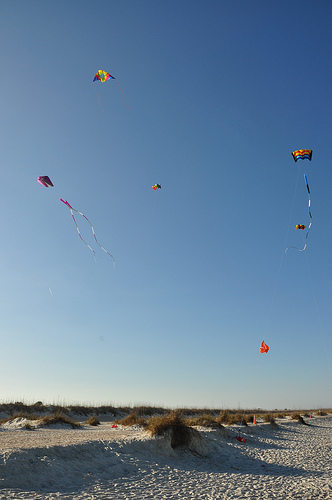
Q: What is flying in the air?
A: Kites.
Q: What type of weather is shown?
A: Clear.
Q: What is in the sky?
A: Kites.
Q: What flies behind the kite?
A: Tails.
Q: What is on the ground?
A: Sand.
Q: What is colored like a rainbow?
A: Kites.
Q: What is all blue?
A: Sky.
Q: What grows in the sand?
A: Beach grass.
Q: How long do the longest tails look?
A: 6 feet.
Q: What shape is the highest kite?
A: Triangle.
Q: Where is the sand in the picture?
A: On the ground.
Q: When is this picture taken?
A: Daytime.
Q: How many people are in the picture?
A: None.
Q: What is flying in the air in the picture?
A: Kites.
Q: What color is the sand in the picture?
A: White.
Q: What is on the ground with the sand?
A: Plants.